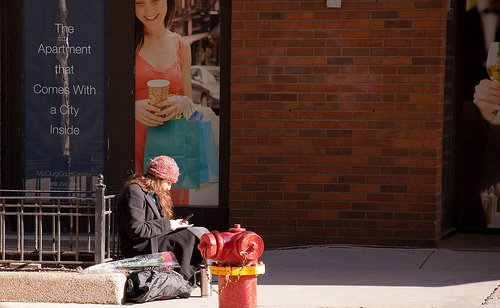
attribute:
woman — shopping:
[132, 0, 221, 203]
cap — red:
[144, 151, 178, 183]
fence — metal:
[2, 171, 125, 269]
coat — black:
[113, 179, 200, 276]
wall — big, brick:
[227, 5, 447, 246]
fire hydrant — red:
[197, 222, 267, 305]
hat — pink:
[146, 150, 181, 185]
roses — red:
[158, 247, 175, 275]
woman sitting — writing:
[119, 153, 218, 275]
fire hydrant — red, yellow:
[191, 208, 270, 306]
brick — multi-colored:
[248, 30, 315, 89]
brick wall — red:
[232, 6, 456, 247]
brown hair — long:
[119, 170, 181, 218]